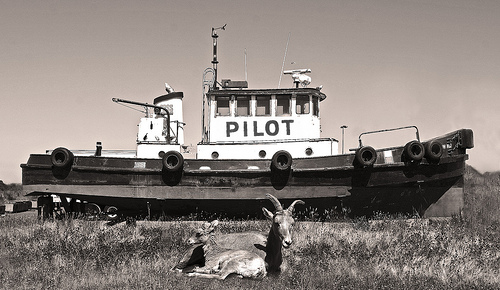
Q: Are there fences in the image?
A: No, there are no fences.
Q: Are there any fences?
A: No, there are no fences.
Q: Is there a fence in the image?
A: No, there are no fences.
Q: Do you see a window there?
A: Yes, there is a window.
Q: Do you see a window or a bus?
A: Yes, there is a window.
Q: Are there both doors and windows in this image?
A: No, there is a window but no doors.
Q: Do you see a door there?
A: No, there are no doors.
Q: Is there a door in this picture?
A: No, there are no doors.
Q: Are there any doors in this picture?
A: No, there are no doors.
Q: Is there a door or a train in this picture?
A: No, there are no doors or trains.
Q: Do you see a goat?
A: Yes, there is a goat.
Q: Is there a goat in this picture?
A: Yes, there is a goat.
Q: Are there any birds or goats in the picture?
A: Yes, there is a goat.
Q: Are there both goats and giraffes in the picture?
A: No, there is a goat but no giraffes.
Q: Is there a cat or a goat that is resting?
A: Yes, the goat is resting.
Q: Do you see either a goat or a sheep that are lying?
A: Yes, the goat is lying.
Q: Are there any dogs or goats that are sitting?
A: Yes, the goat is sitting.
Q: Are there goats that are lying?
A: Yes, there is a goat that is lying.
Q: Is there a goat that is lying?
A: Yes, there is a goat that is lying.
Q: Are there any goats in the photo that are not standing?
A: Yes, there is a goat that is lying.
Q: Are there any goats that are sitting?
A: Yes, there is a goat that is sitting.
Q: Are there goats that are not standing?
A: Yes, there is a goat that is sitting.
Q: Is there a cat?
A: No, there are no cats.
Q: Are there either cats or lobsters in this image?
A: No, there are no cats or lobsters.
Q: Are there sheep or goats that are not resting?
A: No, there is a goat but it is resting.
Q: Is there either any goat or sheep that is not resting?
A: No, there is a goat but it is resting.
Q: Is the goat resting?
A: Yes, the goat is resting.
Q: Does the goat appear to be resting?
A: Yes, the goat is resting.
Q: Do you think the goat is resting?
A: Yes, the goat is resting.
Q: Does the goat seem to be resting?
A: Yes, the goat is resting.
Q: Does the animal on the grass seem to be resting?
A: Yes, the goat is resting.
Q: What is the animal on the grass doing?
A: The goat is resting.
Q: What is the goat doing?
A: The goat is resting.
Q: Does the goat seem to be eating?
A: No, the goat is resting.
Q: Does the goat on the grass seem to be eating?
A: No, the goat is resting.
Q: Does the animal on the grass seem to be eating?
A: No, the goat is resting.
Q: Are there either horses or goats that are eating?
A: No, there is a goat but it is resting.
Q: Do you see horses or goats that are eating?
A: No, there is a goat but it is resting.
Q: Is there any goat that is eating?
A: No, there is a goat but it is resting.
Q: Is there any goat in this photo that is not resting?
A: No, there is a goat but it is resting.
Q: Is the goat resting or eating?
A: The goat is resting.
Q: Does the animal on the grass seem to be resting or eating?
A: The goat is resting.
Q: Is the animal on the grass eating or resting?
A: The goat is resting.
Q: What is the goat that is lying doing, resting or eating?
A: The goat is resting.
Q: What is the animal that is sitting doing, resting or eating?
A: The goat is resting.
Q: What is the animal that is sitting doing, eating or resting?
A: The goat is resting.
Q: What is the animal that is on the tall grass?
A: The animal is a goat.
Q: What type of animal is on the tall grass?
A: The animal is a goat.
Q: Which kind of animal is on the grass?
A: The animal is a goat.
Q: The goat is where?
A: The goat is on the grass.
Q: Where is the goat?
A: The goat is on the grass.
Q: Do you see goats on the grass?
A: Yes, there is a goat on the grass.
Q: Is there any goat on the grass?
A: Yes, there is a goat on the grass.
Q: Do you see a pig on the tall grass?
A: No, there is a goat on the grass.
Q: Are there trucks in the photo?
A: No, there are no trucks.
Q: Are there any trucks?
A: No, there are no trucks.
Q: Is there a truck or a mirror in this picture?
A: No, there are no trucks or mirrors.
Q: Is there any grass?
A: Yes, there is grass.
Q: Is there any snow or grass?
A: Yes, there is grass.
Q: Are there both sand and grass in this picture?
A: No, there is grass but no sand.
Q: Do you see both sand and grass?
A: No, there is grass but no sand.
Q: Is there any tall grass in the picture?
A: Yes, there is tall grass.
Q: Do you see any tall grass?
A: Yes, there is tall grass.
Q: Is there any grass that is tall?
A: Yes, there is grass that is tall.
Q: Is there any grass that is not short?
A: Yes, there is tall grass.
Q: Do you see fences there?
A: No, there are no fences.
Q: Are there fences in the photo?
A: No, there are no fences.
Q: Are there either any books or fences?
A: No, there are no fences or books.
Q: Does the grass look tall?
A: Yes, the grass is tall.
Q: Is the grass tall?
A: Yes, the grass is tall.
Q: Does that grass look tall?
A: Yes, the grass is tall.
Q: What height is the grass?
A: The grass is tall.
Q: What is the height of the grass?
A: The grass is tall.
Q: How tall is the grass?
A: The grass is tall.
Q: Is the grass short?
A: No, the grass is tall.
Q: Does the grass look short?
A: No, the grass is tall.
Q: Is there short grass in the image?
A: No, there is grass but it is tall.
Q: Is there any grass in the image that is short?
A: No, there is grass but it is tall.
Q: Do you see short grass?
A: No, there is grass but it is tall.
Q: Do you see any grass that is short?
A: No, there is grass but it is tall.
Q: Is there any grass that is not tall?
A: No, there is grass but it is tall.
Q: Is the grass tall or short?
A: The grass is tall.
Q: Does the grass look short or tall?
A: The grass is tall.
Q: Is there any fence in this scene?
A: No, there are no fences.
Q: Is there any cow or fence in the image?
A: No, there are no fences or cows.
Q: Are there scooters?
A: No, there are no scooters.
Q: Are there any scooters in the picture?
A: No, there are no scooters.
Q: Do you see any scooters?
A: No, there are no scooters.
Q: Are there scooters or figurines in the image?
A: No, there are no scooters or figurines.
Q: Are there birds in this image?
A: No, there are no birds.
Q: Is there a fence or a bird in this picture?
A: No, there are no birds or fences.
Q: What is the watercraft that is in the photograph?
A: The watercraft is a ship.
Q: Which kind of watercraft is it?
A: The watercraft is a ship.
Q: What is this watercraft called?
A: This is a ship.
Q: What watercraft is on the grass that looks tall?
A: The watercraft is a ship.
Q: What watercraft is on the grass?
A: The watercraft is a ship.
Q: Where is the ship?
A: The ship is on the grass.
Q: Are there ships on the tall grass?
A: Yes, there is a ship on the grass.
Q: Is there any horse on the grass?
A: No, there is a ship on the grass.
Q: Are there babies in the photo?
A: Yes, there is a baby.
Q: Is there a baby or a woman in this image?
A: Yes, there is a baby.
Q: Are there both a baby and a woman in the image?
A: No, there is a baby but no women.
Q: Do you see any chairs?
A: No, there are no chairs.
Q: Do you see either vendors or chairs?
A: No, there are no chairs or vendors.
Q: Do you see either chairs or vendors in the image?
A: No, there are no chairs or vendors.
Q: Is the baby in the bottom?
A: Yes, the baby is in the bottom of the image.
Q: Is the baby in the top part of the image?
A: No, the baby is in the bottom of the image.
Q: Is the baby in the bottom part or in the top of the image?
A: The baby is in the bottom of the image.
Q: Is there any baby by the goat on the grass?
A: Yes, there is a baby by the goat.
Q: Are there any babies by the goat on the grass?
A: Yes, there is a baby by the goat.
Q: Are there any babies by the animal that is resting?
A: Yes, there is a baby by the goat.